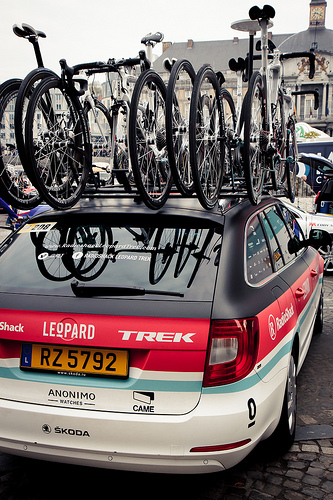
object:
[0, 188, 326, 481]
car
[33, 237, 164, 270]
letters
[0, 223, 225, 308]
window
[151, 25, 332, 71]
roof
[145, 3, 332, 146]
building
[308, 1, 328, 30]
clock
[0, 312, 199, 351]
white letters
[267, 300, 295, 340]
letters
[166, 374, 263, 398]
stripe car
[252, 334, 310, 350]
stripe car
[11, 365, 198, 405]
stripe car